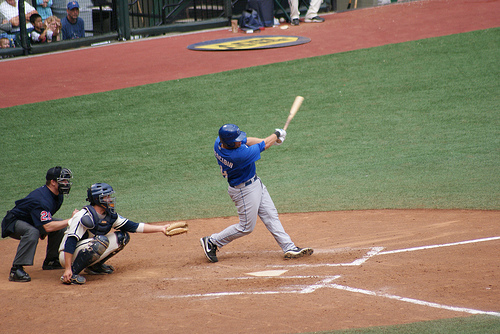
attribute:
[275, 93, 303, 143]
bat — brown, baseball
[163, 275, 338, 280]
line — white, long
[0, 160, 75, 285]
umpire — safety, baseball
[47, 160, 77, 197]
helmet mask — black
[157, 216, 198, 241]
glove — brown, baseball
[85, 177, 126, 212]
helmet — safety, black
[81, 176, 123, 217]
mask — black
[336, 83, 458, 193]
grass — green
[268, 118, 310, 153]
glove — white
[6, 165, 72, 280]
umpire — bent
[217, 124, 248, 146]
helmet — blue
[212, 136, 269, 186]
shirt — blue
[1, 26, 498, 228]
grass — green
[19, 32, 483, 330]
field — baseball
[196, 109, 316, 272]
player — baseball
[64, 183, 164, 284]
catcher — baseball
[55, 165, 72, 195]
guard — face